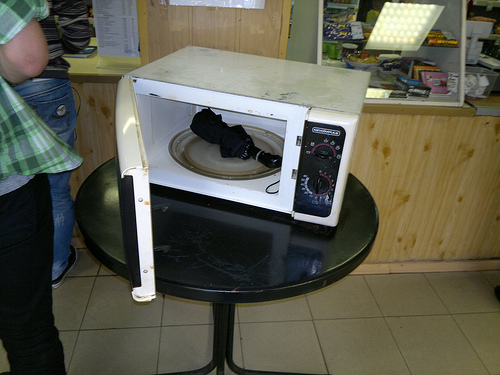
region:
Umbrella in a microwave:
[178, 106, 288, 182]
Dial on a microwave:
[298, 163, 328, 209]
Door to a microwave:
[91, 73, 201, 315]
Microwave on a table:
[119, 46, 385, 274]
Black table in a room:
[88, 146, 405, 351]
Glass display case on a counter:
[312, 1, 497, 95]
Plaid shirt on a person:
[1, 11, 97, 224]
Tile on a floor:
[353, 268, 454, 373]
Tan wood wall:
[385, 125, 483, 289]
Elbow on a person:
[4, 21, 61, 101]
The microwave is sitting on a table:
[96, 22, 386, 293]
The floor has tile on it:
[378, 282, 425, 362]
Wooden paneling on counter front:
[370, 115, 498, 250]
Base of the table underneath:
[180, 293, 266, 371]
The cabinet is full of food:
[316, 0, 478, 120]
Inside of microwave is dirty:
[136, 135, 273, 182]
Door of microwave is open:
[100, 75, 198, 287]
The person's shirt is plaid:
[3, 1, 65, 212]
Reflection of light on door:
[360, 2, 483, 67]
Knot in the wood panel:
[418, 131, 447, 170]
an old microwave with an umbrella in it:
[97, 51, 370, 231]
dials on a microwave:
[303, 116, 350, 216]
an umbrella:
[188, 120, 269, 172]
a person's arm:
[0, 4, 75, 159]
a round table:
[25, 181, 392, 332]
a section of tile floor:
[272, 280, 487, 367]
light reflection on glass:
[335, 0, 457, 47]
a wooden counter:
[360, 120, 490, 240]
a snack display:
[380, 20, 462, 100]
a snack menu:
[75, 0, 142, 51]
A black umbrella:
[190, 111, 286, 181]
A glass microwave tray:
[166, 115, 286, 182]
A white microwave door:
[103, 74, 158, 298]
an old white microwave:
[112, 46, 368, 296]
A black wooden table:
[77, 130, 378, 374]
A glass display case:
[316, 0, 464, 99]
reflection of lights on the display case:
[356, 1, 452, 53]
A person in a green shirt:
[0, 0, 80, 365]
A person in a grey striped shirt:
[11, 0, 84, 290]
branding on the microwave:
[308, 122, 342, 139]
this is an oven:
[145, 52, 341, 215]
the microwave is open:
[131, 72, 329, 198]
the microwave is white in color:
[241, 72, 283, 98]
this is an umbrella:
[199, 119, 254, 154]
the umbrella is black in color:
[213, 120, 254, 154]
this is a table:
[213, 224, 292, 283]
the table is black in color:
[199, 218, 276, 280]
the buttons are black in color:
[297, 128, 337, 201]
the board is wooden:
[418, 133, 465, 222]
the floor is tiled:
[389, 282, 466, 369]